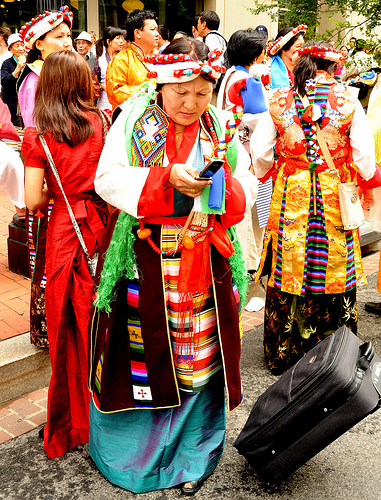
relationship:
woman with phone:
[121, 32, 212, 137] [189, 154, 241, 220]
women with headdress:
[31, 14, 371, 156] [10, 8, 102, 59]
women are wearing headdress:
[31, 14, 371, 156] [10, 8, 102, 59]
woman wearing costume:
[121, 32, 212, 137] [94, 106, 245, 487]